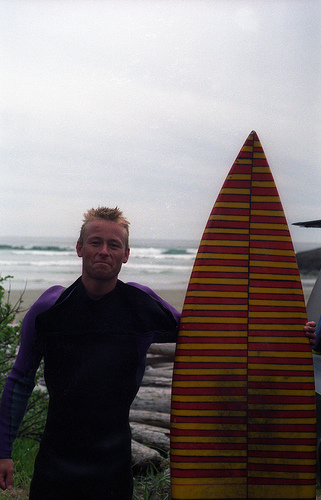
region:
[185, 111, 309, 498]
A multicolored surfboard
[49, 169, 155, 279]
A mans face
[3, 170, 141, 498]
A purple and black wetsuit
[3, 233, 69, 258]
Rocks jutting out of the waves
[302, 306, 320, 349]
A hand gripping the surfboard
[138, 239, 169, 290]
A wave crashing from the ocean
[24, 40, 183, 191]
A cloudy day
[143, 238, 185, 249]
Calm and distant waters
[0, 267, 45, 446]
Some green shrubbery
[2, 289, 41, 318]
Wet beach sand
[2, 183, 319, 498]
a man on the beach holding a colorful surfboard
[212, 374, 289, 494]
a dirty spot on a surfboard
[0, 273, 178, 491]
a surfer's wetsuit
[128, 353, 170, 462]
wooden logs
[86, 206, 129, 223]
a surfer's spiky hairdo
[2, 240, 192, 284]
calm ocean waves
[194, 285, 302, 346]
an interesting striped pattern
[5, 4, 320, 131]
an overcast sky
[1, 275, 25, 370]
a tree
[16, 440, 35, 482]
a grassy area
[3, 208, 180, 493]
surfer wearing a wetsuit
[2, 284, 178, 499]
the wetsuit is purple and black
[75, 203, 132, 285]
the surfer has blonde hair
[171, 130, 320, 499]
the surfboard is in an upright position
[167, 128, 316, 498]
the surfboard is red and yellow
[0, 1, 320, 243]
the sky is cloudy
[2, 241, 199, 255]
the wave is about to hit the shore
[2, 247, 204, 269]
the waves are making foam water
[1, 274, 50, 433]
green weeds behind the surfer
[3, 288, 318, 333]
the sand is smooth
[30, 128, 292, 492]
a man posing with his surfboard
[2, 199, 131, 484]
a man wearing a black wet suit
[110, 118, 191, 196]
an overcast gray sky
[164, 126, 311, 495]
a large yellow and red stripe surfboard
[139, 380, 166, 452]
old driftwood on the ground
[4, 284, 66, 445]
purple and gray sleeve of a wet suit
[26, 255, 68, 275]
the blue ocean behind a man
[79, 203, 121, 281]
the frowning face of a surfer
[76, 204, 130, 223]
spiky blond hair on a head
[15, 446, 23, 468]
green grass on a beach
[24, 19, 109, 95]
Sky is blue in color.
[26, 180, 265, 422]
one man is seen.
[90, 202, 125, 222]
Hair is blonde color.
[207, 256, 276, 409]
Surfing board is red and yellow color.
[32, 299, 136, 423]
Man is wearing black and purple.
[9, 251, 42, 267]
Water is blue in color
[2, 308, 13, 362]
Bush are green in color.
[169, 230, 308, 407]
Man is holding the surfing board.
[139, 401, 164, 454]
Logs are behind the man.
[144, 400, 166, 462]
Logs are grey in color.